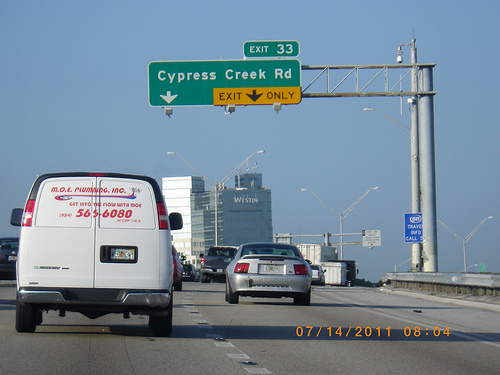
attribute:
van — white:
[11, 168, 187, 334]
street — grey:
[1, 332, 205, 374]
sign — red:
[46, 183, 147, 229]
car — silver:
[222, 238, 314, 309]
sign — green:
[238, 40, 308, 57]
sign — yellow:
[214, 85, 306, 105]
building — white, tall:
[164, 176, 202, 252]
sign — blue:
[403, 213, 423, 242]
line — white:
[192, 311, 278, 374]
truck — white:
[304, 261, 329, 286]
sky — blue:
[15, 33, 145, 134]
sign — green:
[150, 61, 302, 87]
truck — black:
[199, 242, 237, 283]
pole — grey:
[404, 35, 424, 211]